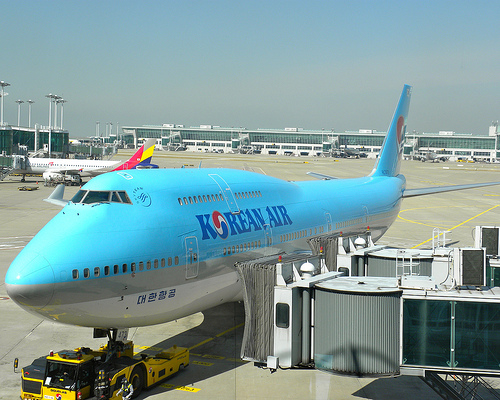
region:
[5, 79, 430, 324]
the plane is blue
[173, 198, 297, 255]
blue letters on plane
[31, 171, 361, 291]
2 levels of windows on plane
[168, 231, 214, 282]
plane door is closed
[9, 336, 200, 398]
yellow vehicle under plane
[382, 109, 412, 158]
red logo on plane's tail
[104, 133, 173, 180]
plane wing is red blue and yellow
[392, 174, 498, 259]
yellow lines on ground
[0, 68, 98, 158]
street lights around building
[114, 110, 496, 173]
airport building in distance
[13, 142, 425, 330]
a blue plane at the airport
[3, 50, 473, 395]
a blue plane at the airport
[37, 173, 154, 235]
windows on a cock pit.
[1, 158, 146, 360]
the front of a jetliner.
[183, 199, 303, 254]
A company name on a jet.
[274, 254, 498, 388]
A walkway on a jet.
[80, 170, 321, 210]
the top of a jetliner.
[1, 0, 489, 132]
a hazy blue sky.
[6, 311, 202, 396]
A yellow towing vehicle.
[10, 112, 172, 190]
A jet parked on a tarmac.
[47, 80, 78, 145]
tall light poles on an airport.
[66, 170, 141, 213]
windows on a large plane.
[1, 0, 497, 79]
a portion of a sky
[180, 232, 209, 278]
the door of a plane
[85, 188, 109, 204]
the window of a plane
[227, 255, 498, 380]
an airport gate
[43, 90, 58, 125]
a tall gray lamp pole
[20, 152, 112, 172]
part of a small white plane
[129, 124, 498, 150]
a long airport building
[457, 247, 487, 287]
a tall ac unit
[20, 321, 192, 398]
a long yellow cart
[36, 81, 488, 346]
a blue and white plane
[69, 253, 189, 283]
a row of windows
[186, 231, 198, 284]
a blue and white door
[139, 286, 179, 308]
blue letters on the side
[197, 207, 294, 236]
writing on the top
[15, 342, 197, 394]
a yellow truck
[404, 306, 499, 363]
a couple of panels of glass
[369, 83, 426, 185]
A rear tail wing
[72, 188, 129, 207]
front windows of the plane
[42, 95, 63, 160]
several pole lights